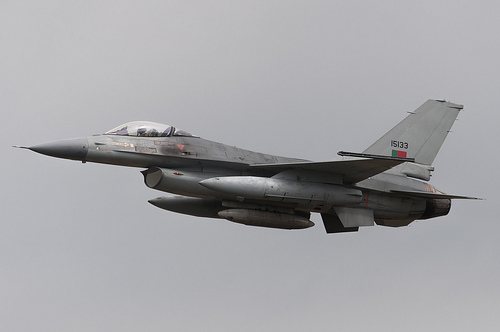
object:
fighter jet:
[11, 96, 488, 234]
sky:
[0, 0, 499, 332]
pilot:
[134, 125, 149, 138]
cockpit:
[105, 117, 195, 141]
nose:
[9, 131, 98, 167]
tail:
[355, 93, 479, 170]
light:
[171, 169, 186, 178]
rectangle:
[391, 147, 410, 159]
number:
[389, 139, 393, 147]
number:
[393, 140, 398, 148]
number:
[397, 141, 400, 149]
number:
[400, 140, 404, 150]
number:
[404, 141, 409, 150]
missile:
[198, 174, 366, 210]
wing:
[240, 150, 418, 185]